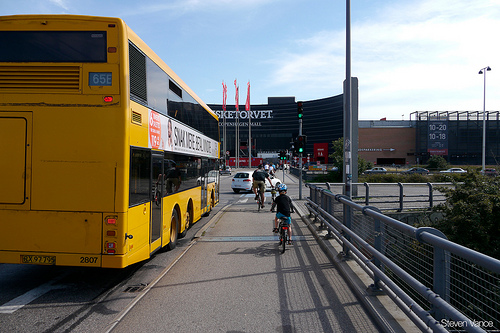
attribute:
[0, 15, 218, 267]
bus — large, yellow